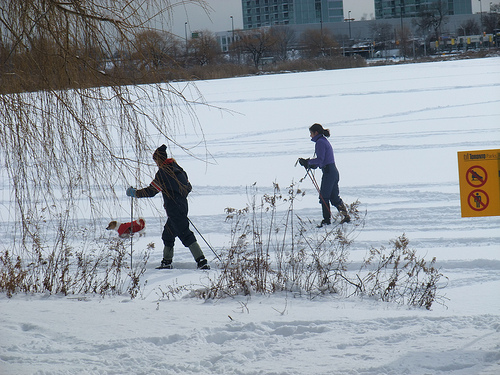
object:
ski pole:
[130, 185, 134, 277]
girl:
[294, 123, 350, 228]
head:
[309, 123, 323, 139]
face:
[310, 130, 318, 139]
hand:
[299, 157, 308, 166]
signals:
[456, 149, 500, 217]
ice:
[0, 56, 499, 375]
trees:
[3, 7, 500, 96]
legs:
[315, 163, 350, 228]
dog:
[106, 217, 148, 242]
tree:
[1, 2, 246, 247]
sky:
[128, 2, 237, 31]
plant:
[218, 193, 276, 298]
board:
[457, 149, 500, 218]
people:
[127, 123, 352, 271]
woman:
[297, 123, 353, 230]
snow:
[0, 54, 500, 375]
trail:
[2, 221, 498, 288]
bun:
[322, 128, 330, 138]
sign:
[463, 152, 500, 211]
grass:
[0, 53, 368, 94]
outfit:
[118, 218, 146, 238]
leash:
[130, 197, 133, 224]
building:
[215, 1, 491, 56]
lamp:
[230, 15, 234, 58]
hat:
[153, 144, 168, 162]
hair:
[309, 123, 331, 138]